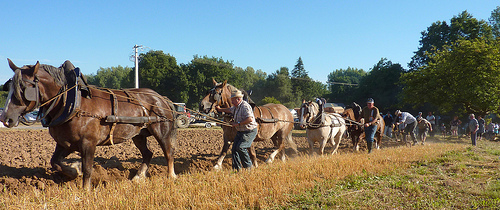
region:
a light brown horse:
[180, 62, 305, 180]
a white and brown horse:
[282, 73, 374, 174]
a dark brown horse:
[8, 43, 205, 194]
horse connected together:
[22, 45, 476, 187]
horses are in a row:
[14, 32, 473, 199]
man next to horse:
[213, 75, 279, 175]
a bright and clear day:
[19, 8, 497, 196]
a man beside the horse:
[200, 74, 275, 181]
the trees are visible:
[71, 31, 308, 108]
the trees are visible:
[105, 36, 387, 131]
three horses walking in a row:
[0, 62, 344, 200]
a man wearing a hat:
[228, 87, 246, 105]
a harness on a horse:
[54, 52, 87, 122]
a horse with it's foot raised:
[50, 155, 78, 185]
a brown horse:
[4, 57, 176, 195]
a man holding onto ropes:
[215, 116, 243, 133]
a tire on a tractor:
[175, 112, 190, 129]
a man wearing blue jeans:
[231, 122, 258, 171]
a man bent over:
[393, 108, 418, 138]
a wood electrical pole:
[133, 37, 143, 87]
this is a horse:
[5, 39, 207, 199]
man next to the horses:
[217, 77, 284, 200]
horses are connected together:
[10, 39, 436, 193]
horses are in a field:
[15, 28, 482, 208]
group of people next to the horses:
[343, 68, 495, 165]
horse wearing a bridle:
[2, 48, 66, 129]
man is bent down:
[388, 100, 424, 143]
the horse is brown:
[2, 65, 180, 175]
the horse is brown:
[203, 83, 308, 160]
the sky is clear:
[29, 8, 308, 68]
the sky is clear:
[28, 17, 266, 51]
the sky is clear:
[43, 22, 340, 96]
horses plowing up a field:
[2, 57, 434, 191]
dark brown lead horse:
[0, 56, 177, 190]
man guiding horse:
[213, 87, 260, 172]